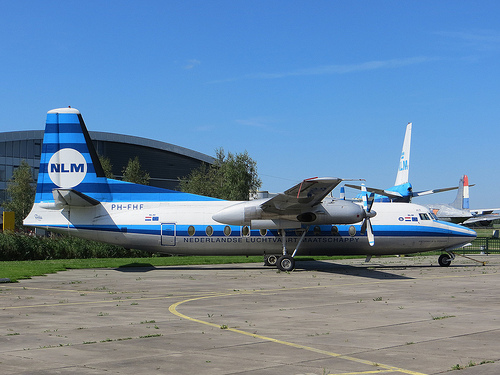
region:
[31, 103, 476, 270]
Blue and white airplane.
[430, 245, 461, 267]
Black wheels on the front of the plane.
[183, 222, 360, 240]
Windows on the side of the plane.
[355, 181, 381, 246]
Propeller on the airplane.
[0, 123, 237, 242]
Building in the background.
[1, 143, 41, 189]
Windows in the side of the building.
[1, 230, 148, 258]
Green hedge on the ground.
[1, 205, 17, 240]
Yellow post behind the green hedge.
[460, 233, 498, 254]
Black iron fence in the background.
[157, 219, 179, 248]
Door on the side of the plane.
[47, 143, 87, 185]
The circle with NLM on the tail of the plane.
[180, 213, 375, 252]
The passenger windows of the plane.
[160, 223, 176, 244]
The back door of the plane.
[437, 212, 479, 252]
The nose of the plane.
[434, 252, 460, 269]
The front wheel of the plane.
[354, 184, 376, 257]
The propeller on the side wing of the plane.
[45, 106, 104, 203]
The tail of the plane that has a striped design on it.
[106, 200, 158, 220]
The letters PH-FHF on the side of the plane.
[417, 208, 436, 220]
The windows on the front of the plane.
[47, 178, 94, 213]
The small wing near the tail of the plane that has the striped design on it.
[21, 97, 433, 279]
blue and white passenger plane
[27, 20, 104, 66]
white clouds in blue sky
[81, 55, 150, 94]
white clouds in blue sky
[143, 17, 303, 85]
white clouds in blue sky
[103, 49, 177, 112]
white clouds in blue sky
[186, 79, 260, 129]
white clouds in blue sky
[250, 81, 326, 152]
white clouds in blue sky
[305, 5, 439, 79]
white clouds in blue sky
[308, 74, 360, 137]
white clouds in blue sky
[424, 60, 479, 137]
white clouds in blue sky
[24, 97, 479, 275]
airplane on the runway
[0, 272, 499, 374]
runway where the planes are parked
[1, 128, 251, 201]
airport where passengers travel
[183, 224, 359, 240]
windows on the side of a plane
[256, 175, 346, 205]
wing of an airplane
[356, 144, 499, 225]
airplanes on the tarmac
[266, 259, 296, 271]
Wheels of the airplane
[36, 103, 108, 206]
tail of airplane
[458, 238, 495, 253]
fence beside plane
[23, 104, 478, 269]
airplane parked on runway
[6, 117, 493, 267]
Blue, white, and gray plane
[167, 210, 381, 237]
Row of windows on plane's side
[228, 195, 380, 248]
Turboprop engine on wing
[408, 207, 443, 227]
Small cockpit windows on plane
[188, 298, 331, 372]
Yellow lines on tarmac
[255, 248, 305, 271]
Round rubber tires on landing gear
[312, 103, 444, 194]
Tall white tail of airliner in background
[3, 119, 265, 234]
Large airplane hanger in background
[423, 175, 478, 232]
Tail of vintage aircraft in backgound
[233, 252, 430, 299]
Shadow cast of plane's wing